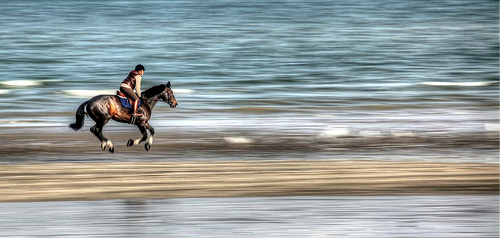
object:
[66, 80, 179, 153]
horse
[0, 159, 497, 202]
sandbar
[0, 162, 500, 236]
ground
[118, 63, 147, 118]
rider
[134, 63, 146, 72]
helmet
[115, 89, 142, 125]
saddle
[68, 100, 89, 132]
tail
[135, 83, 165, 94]
mane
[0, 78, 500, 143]
waves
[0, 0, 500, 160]
water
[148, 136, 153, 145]
part of leg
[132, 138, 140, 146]
part of leg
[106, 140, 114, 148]
part of leg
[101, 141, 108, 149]
part of leg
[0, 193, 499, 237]
water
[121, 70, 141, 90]
vest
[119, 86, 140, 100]
pants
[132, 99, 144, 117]
boots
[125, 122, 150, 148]
leg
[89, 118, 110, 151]
leg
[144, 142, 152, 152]
feet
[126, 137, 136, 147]
feet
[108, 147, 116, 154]
feet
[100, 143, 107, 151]
feet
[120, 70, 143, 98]
shirt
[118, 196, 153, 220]
reflection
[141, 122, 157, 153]
leg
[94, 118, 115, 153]
leg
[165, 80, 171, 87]
ear